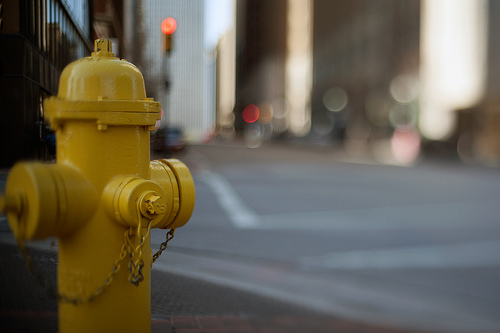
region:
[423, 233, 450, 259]
part f a line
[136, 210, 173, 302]
part of a chain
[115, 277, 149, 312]
part f a chain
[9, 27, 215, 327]
This is an oil hydrant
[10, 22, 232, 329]
This is an oil hydrant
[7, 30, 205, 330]
This is an oil hydrant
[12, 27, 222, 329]
This is an oil hydrant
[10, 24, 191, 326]
This is an oil hydrant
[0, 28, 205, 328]
This is an oil hydrant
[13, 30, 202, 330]
This is an oil hydrant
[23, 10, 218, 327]
This is an oil hydrant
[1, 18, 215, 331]
This is an oil hydrant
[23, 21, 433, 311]
this is in an urban area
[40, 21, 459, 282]
this is a city street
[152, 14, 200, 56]
this is a traffic light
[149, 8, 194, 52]
the traffic light is red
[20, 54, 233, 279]
this is a fire hydrant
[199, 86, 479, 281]
the background is very blurry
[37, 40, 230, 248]
the foreground is in focus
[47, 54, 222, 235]
this is to put out fires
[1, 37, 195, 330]
the yellow fire hydrant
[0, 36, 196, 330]
the fire hydrant on the sidewalk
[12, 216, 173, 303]
the chain hanging from the hydrant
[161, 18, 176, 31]
the red light in the distance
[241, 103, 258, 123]
the red light in the distance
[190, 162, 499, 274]
the blurred white lines on the road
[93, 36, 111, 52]
the piece at the very top of the hydrant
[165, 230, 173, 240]
the link on the chain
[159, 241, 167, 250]
the link on the chain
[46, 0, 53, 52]
A window on a building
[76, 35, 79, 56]
A window on a building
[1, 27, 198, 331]
yellow fire hydrant with painted chains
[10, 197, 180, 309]
yellow chains attached to each cap of a hydrant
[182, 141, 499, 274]
white lines painted on a gray street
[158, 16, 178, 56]
red traffic light at the side of a street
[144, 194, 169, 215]
yellow bolt on the cap of a fire hydrant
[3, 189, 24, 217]
yellow bolt on the cap of a fire hydrant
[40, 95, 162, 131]
yellow seam of the meeting of cap to hydrant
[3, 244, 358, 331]
dark stone sidewalk beside the gray street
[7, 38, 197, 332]
a yellow metal fire hydrant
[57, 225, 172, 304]
the yellow hydrant chain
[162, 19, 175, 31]
the red traffic light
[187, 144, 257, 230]
the white painted line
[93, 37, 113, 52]
the yellow top of the hydrant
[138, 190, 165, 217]
the large yellow bolt of the hydrant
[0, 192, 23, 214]
the yellow bolt